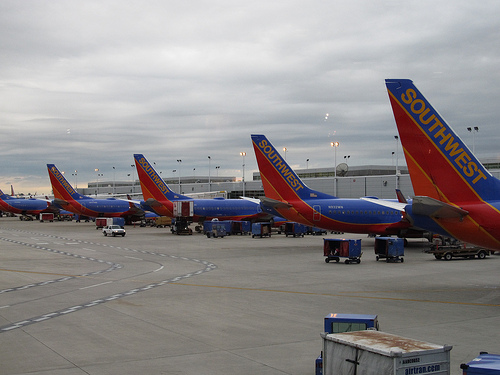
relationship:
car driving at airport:
[88, 217, 140, 248] [13, 77, 478, 369]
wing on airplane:
[3, 197, 49, 209] [130, 151, 291, 236]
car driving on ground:
[102, 224, 129, 238] [2, 216, 498, 373]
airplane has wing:
[247, 132, 413, 239] [247, 128, 327, 218]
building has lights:
[163, 162, 411, 197] [233, 140, 349, 160]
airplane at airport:
[383, 77, 493, 267] [0, 121, 498, 372]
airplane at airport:
[247, 131, 407, 238] [0, 121, 498, 372]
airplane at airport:
[130, 151, 256, 237] [0, 121, 498, 372]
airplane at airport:
[0, 176, 50, 225] [0, 121, 498, 372]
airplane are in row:
[130, 151, 291, 236] [0, 78, 499, 260]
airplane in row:
[383, 77, 500, 261] [0, 78, 499, 260]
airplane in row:
[247, 132, 413, 239] [0, 78, 499, 260]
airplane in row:
[130, 151, 291, 236] [0, 78, 499, 260]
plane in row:
[47, 161, 140, 226] [0, 78, 499, 260]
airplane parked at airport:
[383, 77, 500, 261] [0, 121, 498, 372]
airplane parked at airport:
[247, 132, 413, 239] [0, 121, 498, 372]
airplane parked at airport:
[130, 151, 291, 236] [0, 121, 498, 372]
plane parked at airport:
[47, 161, 140, 226] [0, 121, 498, 372]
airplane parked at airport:
[0, 187, 72, 224] [0, 121, 498, 372]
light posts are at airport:
[226, 139, 352, 172] [0, 121, 498, 372]